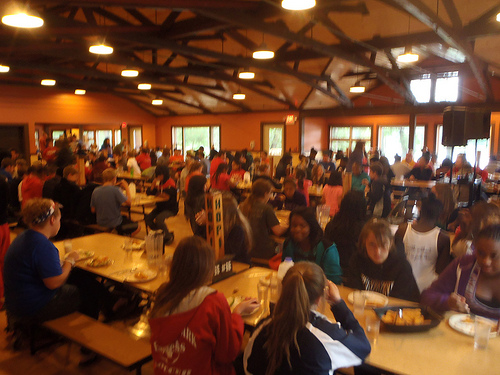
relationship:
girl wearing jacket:
[271, 272, 393, 340] [234, 295, 372, 374]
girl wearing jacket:
[284, 190, 361, 255] [280, 237, 343, 286]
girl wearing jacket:
[428, 222, 498, 332] [416, 252, 498, 317]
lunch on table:
[375, 302, 447, 332] [54, 227, 499, 373]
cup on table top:
[450, 304, 472, 332] [357, 324, 498, 374]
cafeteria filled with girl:
[2, 0, 497, 373] [239, 261, 368, 375]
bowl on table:
[372, 304, 444, 334] [208, 264, 499, 373]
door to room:
[261, 118, 286, 164] [0, 0, 498, 372]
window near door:
[153, 117, 232, 159] [248, 103, 293, 163]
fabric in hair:
[31, 197, 56, 220] [20, 200, 62, 225]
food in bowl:
[390, 312, 421, 319] [373, 302, 437, 327]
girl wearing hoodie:
[149, 235, 261, 373] [148, 282, 242, 374]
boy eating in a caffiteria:
[90, 166, 138, 234] [3, 3, 498, 367]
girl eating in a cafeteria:
[239, 261, 368, 375] [2, 0, 497, 373]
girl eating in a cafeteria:
[143, 235, 246, 375] [2, 0, 497, 373]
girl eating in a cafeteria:
[420, 222, 500, 324] [2, 0, 497, 373]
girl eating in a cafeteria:
[345, 218, 419, 300] [2, 0, 497, 373]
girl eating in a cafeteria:
[280, 205, 342, 287] [2, 0, 497, 373]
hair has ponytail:
[259, 257, 328, 372] [261, 271, 312, 369]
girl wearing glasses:
[345, 218, 441, 310] [365, 238, 401, 250]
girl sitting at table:
[0, 199, 88, 324] [54, 227, 499, 373]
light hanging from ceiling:
[252, 51, 274, 59] [0, 1, 488, 28]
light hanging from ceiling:
[278, 0, 316, 10] [0, 1, 488, 28]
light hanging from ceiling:
[398, 52, 418, 63] [0, 1, 488, 28]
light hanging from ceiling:
[346, 87, 366, 92] [0, 1, 488, 28]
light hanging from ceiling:
[2, 14, 44, 27] [0, 1, 488, 28]